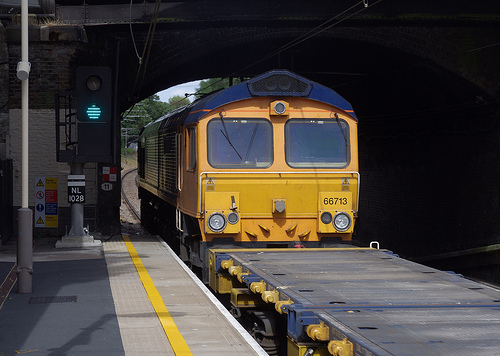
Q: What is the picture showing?
A: It is showing a tunnel.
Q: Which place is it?
A: It is a tunnel.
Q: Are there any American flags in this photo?
A: No, there are no American flags.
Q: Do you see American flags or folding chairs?
A: No, there are no American flags or folding chairs.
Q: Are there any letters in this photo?
A: Yes, there are letters.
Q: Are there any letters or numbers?
A: Yes, there are letters.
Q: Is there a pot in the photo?
A: No, there are no pots.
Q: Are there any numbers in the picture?
A: Yes, there are numbers.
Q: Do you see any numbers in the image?
A: Yes, there are numbers.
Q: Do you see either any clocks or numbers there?
A: Yes, there are numbers.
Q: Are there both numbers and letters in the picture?
A: Yes, there are both numbers and letters.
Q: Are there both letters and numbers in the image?
A: Yes, there are both numbers and letters.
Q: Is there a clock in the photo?
A: No, there are no clocks.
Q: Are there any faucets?
A: No, there are no faucets.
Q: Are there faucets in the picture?
A: No, there are no faucets.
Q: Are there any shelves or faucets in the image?
A: No, there are no faucets or shelves.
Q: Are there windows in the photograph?
A: Yes, there is a window.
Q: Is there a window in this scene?
A: Yes, there is a window.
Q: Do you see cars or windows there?
A: Yes, there is a window.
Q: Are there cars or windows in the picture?
A: Yes, there is a window.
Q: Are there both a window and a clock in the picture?
A: No, there is a window but no clocks.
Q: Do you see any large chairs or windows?
A: Yes, there is a large window.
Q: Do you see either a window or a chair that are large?
A: Yes, the window is large.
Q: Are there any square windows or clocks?
A: Yes, there is a square window.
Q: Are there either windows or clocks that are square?
A: Yes, the window is square.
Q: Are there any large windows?
A: Yes, there is a large window.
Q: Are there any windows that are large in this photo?
A: Yes, there is a large window.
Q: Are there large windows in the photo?
A: Yes, there is a large window.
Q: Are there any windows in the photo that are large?
A: Yes, there is a window that is large.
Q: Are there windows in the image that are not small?
A: Yes, there is a large window.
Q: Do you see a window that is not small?
A: Yes, there is a large window.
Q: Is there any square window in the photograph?
A: Yes, there is a square window.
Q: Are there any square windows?
A: Yes, there is a square window.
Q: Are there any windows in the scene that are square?
A: Yes, there is a window that is square.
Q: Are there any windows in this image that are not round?
A: Yes, there is a square window.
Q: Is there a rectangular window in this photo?
A: Yes, there is a rectangular window.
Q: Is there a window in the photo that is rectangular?
A: Yes, there is a window that is rectangular.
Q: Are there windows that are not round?
A: Yes, there is a rectangular window.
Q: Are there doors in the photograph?
A: No, there are no doors.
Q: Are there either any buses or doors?
A: No, there are no doors or buses.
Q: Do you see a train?
A: Yes, there is a train.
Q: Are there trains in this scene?
A: Yes, there is a train.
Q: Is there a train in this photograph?
A: Yes, there is a train.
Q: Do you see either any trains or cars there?
A: Yes, there is a train.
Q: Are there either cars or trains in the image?
A: Yes, there is a train.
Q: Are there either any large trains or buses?
A: Yes, there is a large train.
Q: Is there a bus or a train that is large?
A: Yes, the train is large.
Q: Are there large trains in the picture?
A: Yes, there is a large train.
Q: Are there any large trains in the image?
A: Yes, there is a large train.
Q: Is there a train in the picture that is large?
A: Yes, there is a train that is large.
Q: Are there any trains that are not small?
A: Yes, there is a large train.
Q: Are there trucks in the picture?
A: No, there are no trucks.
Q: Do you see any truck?
A: No, there are no trucks.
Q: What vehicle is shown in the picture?
A: The vehicle is a train.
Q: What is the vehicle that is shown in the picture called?
A: The vehicle is a train.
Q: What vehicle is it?
A: The vehicle is a train.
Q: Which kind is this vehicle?
A: This is a train.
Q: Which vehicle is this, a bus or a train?
A: This is a train.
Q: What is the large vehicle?
A: The vehicle is a train.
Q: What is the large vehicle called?
A: The vehicle is a train.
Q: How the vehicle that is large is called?
A: The vehicle is a train.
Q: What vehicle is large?
A: The vehicle is a train.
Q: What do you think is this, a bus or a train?
A: This is a train.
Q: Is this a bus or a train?
A: This is a train.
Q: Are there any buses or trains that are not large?
A: No, there is a train but it is large.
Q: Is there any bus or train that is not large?
A: No, there is a train but it is large.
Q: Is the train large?
A: Yes, the train is large.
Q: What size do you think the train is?
A: The train is large.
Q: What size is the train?
A: The train is large.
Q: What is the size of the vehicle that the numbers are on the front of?
A: The train is large.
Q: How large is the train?
A: The train is large.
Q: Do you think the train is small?
A: No, the train is large.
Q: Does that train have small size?
A: No, the train is large.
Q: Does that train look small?
A: No, the train is large.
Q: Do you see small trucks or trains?
A: No, there is a train but it is large.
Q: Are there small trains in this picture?
A: No, there is a train but it is large.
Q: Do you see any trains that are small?
A: No, there is a train but it is large.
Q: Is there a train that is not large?
A: No, there is a train but it is large.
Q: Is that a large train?
A: Yes, that is a large train.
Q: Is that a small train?
A: No, that is a large train.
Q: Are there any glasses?
A: No, there are no glasses.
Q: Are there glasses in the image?
A: No, there are no glasses.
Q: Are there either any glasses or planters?
A: No, there are no glasses or planters.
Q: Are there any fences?
A: No, there are no fences.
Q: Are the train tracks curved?
A: Yes, the train tracks are curved.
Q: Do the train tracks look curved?
A: Yes, the train tracks are curved.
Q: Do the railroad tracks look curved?
A: Yes, the railroad tracks are curved.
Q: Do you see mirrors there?
A: No, there are no mirrors.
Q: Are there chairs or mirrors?
A: No, there are no mirrors or chairs.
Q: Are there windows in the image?
A: Yes, there is a window.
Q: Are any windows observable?
A: Yes, there is a window.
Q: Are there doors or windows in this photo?
A: Yes, there is a window.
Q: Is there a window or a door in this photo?
A: Yes, there is a window.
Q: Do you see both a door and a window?
A: No, there is a window but no doors.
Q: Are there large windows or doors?
A: Yes, there is a large window.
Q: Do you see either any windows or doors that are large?
A: Yes, the window is large.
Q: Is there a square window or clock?
A: Yes, there is a square window.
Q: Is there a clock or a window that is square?
A: Yes, the window is square.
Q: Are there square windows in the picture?
A: Yes, there is a square window.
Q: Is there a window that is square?
A: Yes, there is a window that is square.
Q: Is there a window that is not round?
A: Yes, there is a square window.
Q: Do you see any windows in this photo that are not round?
A: Yes, there is a square window.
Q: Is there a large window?
A: Yes, there is a large window.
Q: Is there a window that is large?
A: Yes, there is a window that is large.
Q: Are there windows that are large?
A: Yes, there is a window that is large.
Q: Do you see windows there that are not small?
A: Yes, there is a large window.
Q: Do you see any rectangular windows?
A: Yes, there is a rectangular window.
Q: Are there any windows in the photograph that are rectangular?
A: Yes, there is a window that is rectangular.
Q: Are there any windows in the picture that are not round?
A: Yes, there is a rectangular window.